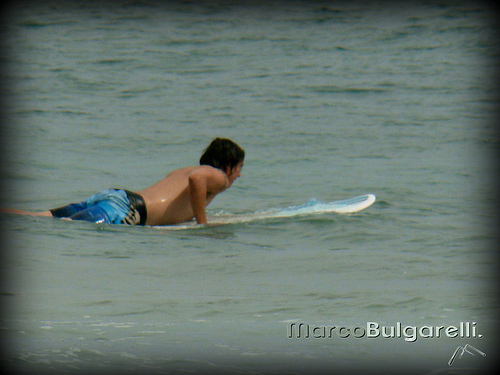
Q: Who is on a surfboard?
A: A man.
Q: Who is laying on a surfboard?
A: A man.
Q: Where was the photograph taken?
A: On the ocean.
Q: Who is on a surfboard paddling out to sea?
A: A man.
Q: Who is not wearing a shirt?
A: The man.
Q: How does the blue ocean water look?
A: Calm.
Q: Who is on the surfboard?
A: A young man.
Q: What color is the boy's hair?
A: Brown.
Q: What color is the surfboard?
A: White.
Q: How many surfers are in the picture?
A: One.